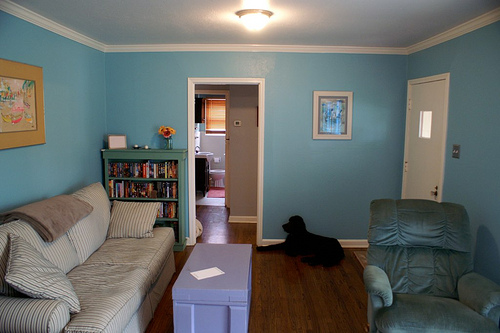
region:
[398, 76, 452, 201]
Door to outside is white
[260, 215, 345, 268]
Black dog laying on the floor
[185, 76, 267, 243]
Doorway to other parts of the house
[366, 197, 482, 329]
Blue recliner facing away from the door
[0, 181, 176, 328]
White couch with dark stripes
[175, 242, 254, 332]
Coffee table in middle of room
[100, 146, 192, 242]
Turquois bookcase in back of room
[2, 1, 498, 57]
Ceiling is painted white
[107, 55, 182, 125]
Walls are painted blue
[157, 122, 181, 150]
Vase with yellow flowers on bookcase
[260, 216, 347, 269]
A black dog in the photo.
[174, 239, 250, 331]
A gray table in the photo.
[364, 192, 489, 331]
A light green seat in the photo.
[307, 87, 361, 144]
A wall hanging in the photo.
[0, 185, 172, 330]
A cream and black couch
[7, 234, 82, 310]
A pillow on the couch.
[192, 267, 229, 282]
A paper sheet on the table.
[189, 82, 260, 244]
An opened door in the photo.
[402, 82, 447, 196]
A closed door in the photo.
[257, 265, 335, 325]
A wooden floor in the photo.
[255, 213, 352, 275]
A black dog lying on the floor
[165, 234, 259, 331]
A small purple coffee table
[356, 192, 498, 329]
A large plush easy chair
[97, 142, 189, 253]
Part of a short green bookshelf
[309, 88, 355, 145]
A piece of art on the wall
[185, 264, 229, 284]
A piece of paper on the table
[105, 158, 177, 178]
Books on the bookshelf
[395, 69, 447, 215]
A white door with a window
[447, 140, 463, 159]
Power switches on the wall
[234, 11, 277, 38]
A bright ceiling light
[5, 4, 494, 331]
a living room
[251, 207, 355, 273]
a dog lying on the floor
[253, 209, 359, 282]
the dog is laying on the floor in the living room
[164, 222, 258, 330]
a plastic coffee table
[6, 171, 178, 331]
a tan striped couch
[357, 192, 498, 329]
a blue reclining chair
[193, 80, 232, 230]
a bathroom is seen through the doorway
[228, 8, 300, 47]
a light is powered on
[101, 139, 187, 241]
a green bookshelf along a wall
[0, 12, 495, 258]
the walls are blue with white moldings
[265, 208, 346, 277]
black dog laying by blue walls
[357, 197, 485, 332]
blue reclining chair by door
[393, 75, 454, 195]
white door with small window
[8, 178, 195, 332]
light colored couch against wall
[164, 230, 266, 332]
purple coffee table in front of couch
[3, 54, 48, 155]
painting hanging above couch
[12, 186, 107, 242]
blanket on back of couch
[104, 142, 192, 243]
green bookcase filled with books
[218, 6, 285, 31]
lit ceiling light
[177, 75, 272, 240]
white doorframe leading to another room